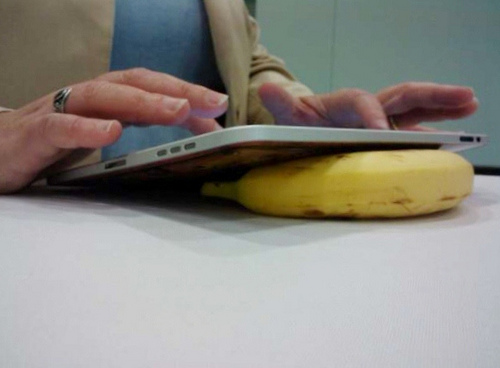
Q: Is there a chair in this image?
A: No, there are no chairs.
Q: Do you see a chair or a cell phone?
A: No, there are no chairs or cell phones.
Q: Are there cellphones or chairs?
A: No, there are no chairs or cellphones.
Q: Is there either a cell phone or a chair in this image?
A: No, there are no chairs or cell phones.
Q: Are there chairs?
A: No, there are no chairs.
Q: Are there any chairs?
A: No, there are no chairs.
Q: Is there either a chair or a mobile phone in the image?
A: No, there are no chairs or cell phones.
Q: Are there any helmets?
A: No, there are no helmets.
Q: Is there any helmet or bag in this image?
A: No, there are no helmets or bags.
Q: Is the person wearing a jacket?
A: Yes, the person is wearing a jacket.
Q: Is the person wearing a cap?
A: No, the person is wearing a jacket.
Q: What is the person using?
A: The person is using a tablet.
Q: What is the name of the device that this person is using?
A: The device is a tablet.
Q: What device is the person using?
A: The person is using a tablet.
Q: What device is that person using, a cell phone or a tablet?
A: The person is using a tablet.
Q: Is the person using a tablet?
A: Yes, the person is using a tablet.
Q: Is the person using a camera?
A: No, the person is using a tablet.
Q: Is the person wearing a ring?
A: Yes, the person is wearing a ring.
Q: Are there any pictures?
A: No, there are no pictures.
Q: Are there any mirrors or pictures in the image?
A: No, there are no pictures or mirrors.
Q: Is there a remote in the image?
A: No, there are no remote controls.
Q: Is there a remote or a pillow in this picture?
A: No, there are no remote controls or pillows.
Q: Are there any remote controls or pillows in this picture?
A: No, there are no remote controls or pillows.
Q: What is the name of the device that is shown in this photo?
A: The device is a tablet.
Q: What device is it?
A: The device is a tablet.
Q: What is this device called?
A: This is a tablet.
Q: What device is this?
A: This is a tablet.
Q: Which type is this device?
A: This is a tablet.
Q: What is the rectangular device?
A: The device is a tablet.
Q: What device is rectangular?
A: The device is a tablet.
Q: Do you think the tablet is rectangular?
A: Yes, the tablet is rectangular.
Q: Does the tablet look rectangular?
A: Yes, the tablet is rectangular.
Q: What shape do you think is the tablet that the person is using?
A: The tablet is rectangular.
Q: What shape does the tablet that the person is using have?
A: The tablet has rectangular shape.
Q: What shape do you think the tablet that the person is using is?
A: The tablet is rectangular.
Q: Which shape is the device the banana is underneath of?
A: The tablet is rectangular.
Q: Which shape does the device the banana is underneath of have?
A: The tablet has rectangular shape.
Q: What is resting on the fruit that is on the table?
A: The tablet is resting on the banana.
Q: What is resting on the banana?
A: The tablet is resting on the banana.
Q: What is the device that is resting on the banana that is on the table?
A: The device is a tablet.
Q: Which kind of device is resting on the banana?
A: The device is a tablet.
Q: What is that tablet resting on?
A: The tablet is resting on the banana.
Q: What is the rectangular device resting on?
A: The tablet is resting on the banana.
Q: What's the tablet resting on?
A: The tablet is resting on the banana.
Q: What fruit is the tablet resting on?
A: The tablet is resting on the banana.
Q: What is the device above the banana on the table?
A: The device is a tablet.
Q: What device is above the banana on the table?
A: The device is a tablet.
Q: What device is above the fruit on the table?
A: The device is a tablet.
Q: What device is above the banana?
A: The device is a tablet.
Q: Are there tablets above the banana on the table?
A: Yes, there is a tablet above the banana.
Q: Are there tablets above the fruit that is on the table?
A: Yes, there is a tablet above the banana.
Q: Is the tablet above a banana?
A: Yes, the tablet is above a banana.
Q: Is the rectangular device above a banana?
A: Yes, the tablet is above a banana.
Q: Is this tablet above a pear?
A: No, the tablet is above a banana.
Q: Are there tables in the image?
A: Yes, there is a table.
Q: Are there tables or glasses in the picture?
A: Yes, there is a table.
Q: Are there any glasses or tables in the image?
A: Yes, there is a table.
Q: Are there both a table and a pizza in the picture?
A: No, there is a table but no pizzas.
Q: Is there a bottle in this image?
A: No, there are no bottles.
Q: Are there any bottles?
A: No, there are no bottles.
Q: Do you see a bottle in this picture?
A: No, there are no bottles.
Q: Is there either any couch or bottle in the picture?
A: No, there are no bottles or couches.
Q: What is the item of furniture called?
A: The piece of furniture is a table.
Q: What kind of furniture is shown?
A: The furniture is a table.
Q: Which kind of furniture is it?
A: The piece of furniture is a table.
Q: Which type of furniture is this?
A: This is a table.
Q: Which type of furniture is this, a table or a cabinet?
A: This is a table.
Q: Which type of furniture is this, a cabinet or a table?
A: This is a table.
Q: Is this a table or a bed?
A: This is a table.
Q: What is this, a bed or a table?
A: This is a table.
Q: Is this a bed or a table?
A: This is a table.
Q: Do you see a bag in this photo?
A: No, there are no bags.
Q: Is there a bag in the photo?
A: No, there are no bags.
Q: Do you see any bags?
A: No, there are no bags.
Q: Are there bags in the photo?
A: No, there are no bags.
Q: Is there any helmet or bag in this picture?
A: No, there are no bags or helmets.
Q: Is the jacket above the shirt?
A: Yes, the jacket is above the shirt.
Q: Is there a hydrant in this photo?
A: No, there are no fire hydrants.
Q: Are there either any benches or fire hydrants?
A: No, there are no fire hydrants or benches.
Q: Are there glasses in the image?
A: No, there are no glasses.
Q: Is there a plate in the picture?
A: No, there are no plates.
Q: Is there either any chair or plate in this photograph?
A: No, there are no plates or chairs.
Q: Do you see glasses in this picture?
A: No, there are no glasses.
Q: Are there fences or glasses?
A: No, there are no glasses or fences.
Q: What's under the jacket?
A: The shirt is under the jacket.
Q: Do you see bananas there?
A: Yes, there is a banana.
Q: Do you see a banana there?
A: Yes, there is a banana.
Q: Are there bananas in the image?
A: Yes, there is a banana.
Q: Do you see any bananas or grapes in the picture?
A: Yes, there is a banana.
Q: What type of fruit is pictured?
A: The fruit is a banana.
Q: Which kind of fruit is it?
A: The fruit is a banana.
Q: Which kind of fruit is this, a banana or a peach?
A: That is a banana.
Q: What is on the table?
A: The banana is on the table.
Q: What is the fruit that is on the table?
A: The fruit is a banana.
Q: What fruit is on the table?
A: The fruit is a banana.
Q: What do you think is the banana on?
A: The banana is on the table.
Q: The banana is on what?
A: The banana is on the table.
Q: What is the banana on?
A: The banana is on the table.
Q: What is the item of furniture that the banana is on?
A: The piece of furniture is a table.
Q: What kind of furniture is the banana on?
A: The banana is on the table.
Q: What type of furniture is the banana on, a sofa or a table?
A: The banana is on a table.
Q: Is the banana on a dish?
A: No, the banana is on a table.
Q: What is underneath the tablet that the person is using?
A: The banana is underneath the tablet.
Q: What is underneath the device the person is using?
A: The banana is underneath the tablet.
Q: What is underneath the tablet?
A: The banana is underneath the tablet.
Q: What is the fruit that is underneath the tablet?
A: The fruit is a banana.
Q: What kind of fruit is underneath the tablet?
A: The fruit is a banana.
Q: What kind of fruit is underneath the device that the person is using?
A: The fruit is a banana.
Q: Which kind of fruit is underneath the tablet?
A: The fruit is a banana.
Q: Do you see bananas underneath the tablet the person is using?
A: Yes, there is a banana underneath the tablet.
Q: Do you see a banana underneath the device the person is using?
A: Yes, there is a banana underneath the tablet.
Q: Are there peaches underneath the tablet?
A: No, there is a banana underneath the tablet.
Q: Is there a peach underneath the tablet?
A: No, there is a banana underneath the tablet.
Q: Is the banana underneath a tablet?
A: Yes, the banana is underneath a tablet.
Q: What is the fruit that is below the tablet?
A: The fruit is a banana.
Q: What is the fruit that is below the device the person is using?
A: The fruit is a banana.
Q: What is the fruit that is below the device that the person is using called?
A: The fruit is a banana.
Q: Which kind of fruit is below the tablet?
A: The fruit is a banana.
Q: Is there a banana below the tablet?
A: Yes, there is a banana below the tablet.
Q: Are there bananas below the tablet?
A: Yes, there is a banana below the tablet.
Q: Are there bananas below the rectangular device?
A: Yes, there is a banana below the tablet.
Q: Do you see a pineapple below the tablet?
A: No, there is a banana below the tablet.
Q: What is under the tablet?
A: The banana is under the tablet.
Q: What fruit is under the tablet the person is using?
A: The fruit is a banana.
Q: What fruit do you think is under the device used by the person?
A: The fruit is a banana.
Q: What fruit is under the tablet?
A: The fruit is a banana.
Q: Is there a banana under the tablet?
A: Yes, there is a banana under the tablet.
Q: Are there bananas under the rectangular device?
A: Yes, there is a banana under the tablet.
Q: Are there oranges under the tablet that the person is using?
A: No, there is a banana under the tablet.